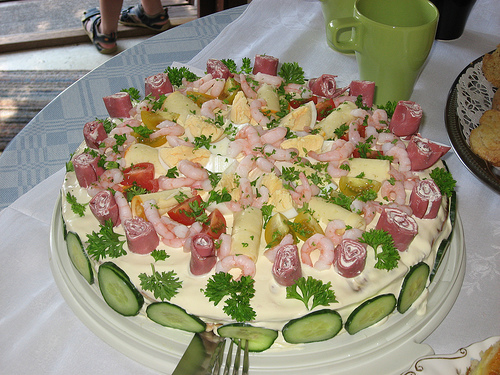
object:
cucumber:
[396, 260, 432, 318]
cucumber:
[345, 293, 394, 333]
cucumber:
[280, 308, 347, 346]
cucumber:
[95, 260, 140, 318]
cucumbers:
[216, 323, 277, 353]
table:
[0, 1, 497, 375]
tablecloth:
[0, 0, 500, 375]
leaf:
[199, 270, 257, 323]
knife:
[167, 327, 209, 375]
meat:
[123, 215, 161, 256]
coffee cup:
[328, 2, 439, 110]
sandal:
[115, 3, 171, 34]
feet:
[77, 3, 123, 58]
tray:
[46, 106, 467, 375]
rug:
[0, 62, 90, 153]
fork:
[207, 338, 250, 373]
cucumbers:
[343, 292, 395, 334]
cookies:
[466, 52, 500, 161]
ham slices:
[69, 152, 96, 188]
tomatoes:
[167, 194, 228, 241]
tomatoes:
[288, 95, 334, 120]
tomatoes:
[343, 124, 376, 157]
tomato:
[118, 162, 158, 192]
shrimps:
[142, 211, 199, 248]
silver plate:
[445, 49, 500, 192]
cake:
[52, 54, 465, 366]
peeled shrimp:
[213, 252, 257, 284]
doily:
[452, 53, 483, 129]